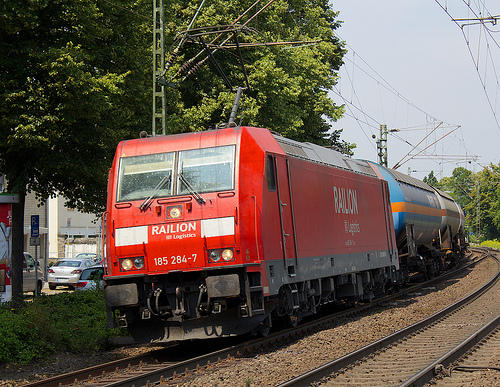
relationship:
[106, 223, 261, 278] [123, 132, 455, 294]
lights on engine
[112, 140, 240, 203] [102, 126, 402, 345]
windshield of engine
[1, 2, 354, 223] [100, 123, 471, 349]
tree near train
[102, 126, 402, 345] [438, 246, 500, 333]
engine on track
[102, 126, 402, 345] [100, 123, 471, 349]
engine of train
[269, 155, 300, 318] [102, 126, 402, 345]
steps of engine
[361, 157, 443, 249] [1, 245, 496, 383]
tank on tracks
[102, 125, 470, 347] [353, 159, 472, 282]
train pulls tank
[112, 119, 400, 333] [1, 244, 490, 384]
train on track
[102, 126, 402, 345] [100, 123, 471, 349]
engine on train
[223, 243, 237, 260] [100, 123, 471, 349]
headlight on train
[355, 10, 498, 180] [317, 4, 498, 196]
clouds in sky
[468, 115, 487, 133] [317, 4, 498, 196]
white clouds in sky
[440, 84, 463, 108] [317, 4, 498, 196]
white clouds in sky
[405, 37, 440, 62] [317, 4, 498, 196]
white clouds in sky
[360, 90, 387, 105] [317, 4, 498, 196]
white clouds in sky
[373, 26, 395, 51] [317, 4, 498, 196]
white clouds in sky